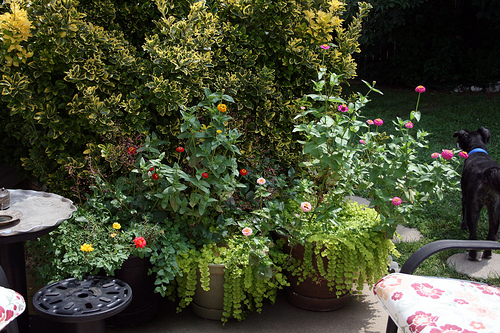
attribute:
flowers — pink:
[429, 149, 468, 166]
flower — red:
[133, 234, 147, 249]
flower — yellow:
[79, 241, 96, 255]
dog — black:
[450, 125, 500, 261]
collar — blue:
[465, 145, 489, 158]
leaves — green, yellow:
[60, 51, 112, 95]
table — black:
[0, 186, 78, 332]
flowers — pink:
[364, 115, 386, 129]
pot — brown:
[282, 240, 354, 315]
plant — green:
[310, 201, 399, 297]